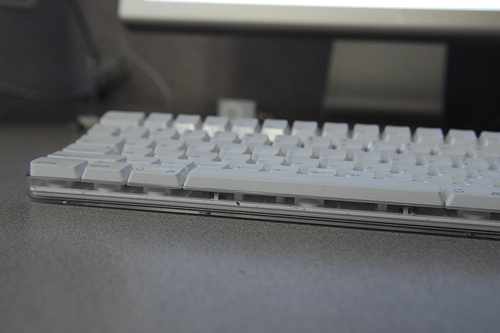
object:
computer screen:
[117, 0, 500, 10]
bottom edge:
[116, 0, 500, 40]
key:
[29, 156, 89, 179]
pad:
[46, 181, 66, 188]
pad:
[97, 184, 115, 194]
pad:
[146, 188, 165, 196]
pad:
[296, 199, 318, 207]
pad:
[462, 211, 488, 219]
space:
[70, 182, 94, 190]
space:
[120, 185, 142, 194]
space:
[171, 189, 214, 198]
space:
[219, 192, 234, 200]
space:
[243, 194, 276, 203]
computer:
[22, 0, 500, 244]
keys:
[99, 110, 146, 131]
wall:
[258, 42, 316, 112]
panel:
[28, 175, 500, 239]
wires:
[123, 51, 171, 110]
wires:
[55, 56, 123, 100]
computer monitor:
[116, 0, 498, 39]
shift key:
[46, 151, 127, 164]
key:
[479, 131, 499, 148]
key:
[353, 124, 381, 140]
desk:
[4, 107, 497, 333]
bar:
[444, 184, 498, 212]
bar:
[81, 159, 131, 184]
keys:
[144, 113, 174, 130]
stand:
[323, 39, 447, 117]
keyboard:
[26, 109, 499, 239]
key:
[202, 115, 232, 136]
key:
[259, 118, 291, 141]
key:
[321, 122, 349, 136]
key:
[382, 125, 411, 141]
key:
[446, 129, 478, 145]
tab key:
[62, 142, 114, 155]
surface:
[6, 118, 495, 330]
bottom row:
[27, 158, 500, 216]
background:
[7, 7, 226, 122]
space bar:
[181, 164, 443, 207]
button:
[127, 165, 188, 190]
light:
[172, 124, 293, 142]